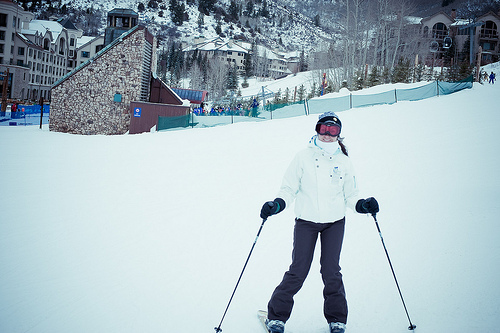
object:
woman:
[258, 110, 379, 333]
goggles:
[315, 121, 343, 137]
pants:
[266, 216, 349, 325]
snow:
[0, 62, 499, 332]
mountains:
[1, 0, 336, 52]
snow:
[0, 0, 497, 51]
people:
[249, 99, 260, 118]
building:
[168, 86, 209, 117]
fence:
[155, 74, 473, 132]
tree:
[346, 0, 360, 91]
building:
[48, 22, 193, 136]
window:
[18, 47, 25, 55]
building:
[0, 0, 85, 101]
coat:
[275, 135, 367, 225]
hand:
[362, 196, 380, 214]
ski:
[365, 200, 419, 333]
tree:
[214, 20, 225, 35]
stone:
[90, 92, 95, 97]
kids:
[488, 71, 496, 84]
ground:
[0, 61, 500, 333]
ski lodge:
[368, 8, 500, 68]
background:
[0, 1, 499, 136]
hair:
[316, 116, 349, 158]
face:
[318, 120, 339, 143]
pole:
[212, 202, 275, 333]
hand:
[260, 200, 280, 219]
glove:
[355, 196, 381, 215]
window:
[43, 37, 50, 52]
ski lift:
[442, 36, 453, 49]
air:
[0, 0, 500, 74]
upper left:
[0, 0, 119, 84]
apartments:
[180, 36, 302, 80]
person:
[483, 71, 490, 82]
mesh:
[395, 79, 439, 103]